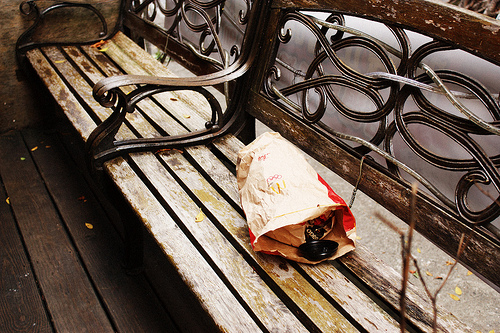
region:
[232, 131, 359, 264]
Brown McDonalds bag on bench.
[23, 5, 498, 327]
Bench on the wooden porch.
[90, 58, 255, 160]
Black metal arm on bench.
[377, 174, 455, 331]
Twigs in the forefront.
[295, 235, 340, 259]
Black plastic coffee lid.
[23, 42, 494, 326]
Wooden slats in the bench.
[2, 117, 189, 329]
Wooden floor boards.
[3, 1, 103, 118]
Brick wall at the end of the bench.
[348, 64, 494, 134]
Tube lighting inter wound in bench.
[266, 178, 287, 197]
Yellow McDonalds logo on bag.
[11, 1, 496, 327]
Old wooden park bench with peeling paint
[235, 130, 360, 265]
Bag of trash on a park bench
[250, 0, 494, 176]
Light strings woven through the back of a bench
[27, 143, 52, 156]
Cigarette butt on the ground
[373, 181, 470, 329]
Small tree branches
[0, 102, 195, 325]
Wood boards under a park bench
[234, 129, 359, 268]
Paper McDonald's bag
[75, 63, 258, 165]
Metal arm rest on a park bench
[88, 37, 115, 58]
Red leaf from a tree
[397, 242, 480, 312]
Multicolored tree leaves on concrete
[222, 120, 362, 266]
The bag on the bench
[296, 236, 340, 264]
The black lid to the cup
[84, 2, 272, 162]
The middle arm of the bench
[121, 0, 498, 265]
The iron back of the bench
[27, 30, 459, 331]
The wood seat of the bench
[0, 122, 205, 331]
The wood floor of the ground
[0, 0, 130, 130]
The stone wall next to the bench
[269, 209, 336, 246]
The wrapper in the bag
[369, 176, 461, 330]
The blurry stick in front of the bench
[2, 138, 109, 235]
The leaves on the ground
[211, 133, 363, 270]
brown paper bag on bench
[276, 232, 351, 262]
coffe cup top in brown paper bag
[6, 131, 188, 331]
wood floor boards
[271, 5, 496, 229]
metal back of bench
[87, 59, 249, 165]
metal bench handrails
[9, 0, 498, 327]
wood and metal bench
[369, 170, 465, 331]
two tree sticks next to bench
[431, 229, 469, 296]
small, thin tree branch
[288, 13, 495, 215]
abstract metal design on back of bench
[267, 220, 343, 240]
trash inside of brown paper bag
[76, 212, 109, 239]
small yellow leaf on ground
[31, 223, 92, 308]
dark brown wood flooring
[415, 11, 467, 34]
scratches on the bench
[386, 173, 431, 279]
brown twigs near the bench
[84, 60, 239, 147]
brass handle on the bench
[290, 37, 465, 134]
decorative back on the bench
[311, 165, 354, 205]
red sign on bag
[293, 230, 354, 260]
black coffee lid in bag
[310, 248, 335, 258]
shine on the coffee lid